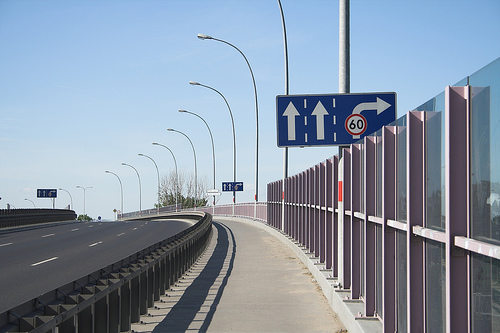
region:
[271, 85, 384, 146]
Blue arrow signs on the freeway.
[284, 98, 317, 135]
The arrows are white.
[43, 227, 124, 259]
White lines in the street.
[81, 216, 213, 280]
Railing on the freeway.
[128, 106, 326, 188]
Light poles lined up on the freeway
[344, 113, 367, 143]
Number "60" in the red circle.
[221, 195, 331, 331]
Sidewalk on the walkway of bridge.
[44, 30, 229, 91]
The sky is clear and blue.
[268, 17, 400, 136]
The sign is posted on the silver pole.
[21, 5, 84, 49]
this is the sky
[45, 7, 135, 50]
the sky is blue in color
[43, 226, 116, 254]
this is the road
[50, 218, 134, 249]
the road is clean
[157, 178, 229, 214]
this is the tree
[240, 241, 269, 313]
this is the pavement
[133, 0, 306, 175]
these are some street lights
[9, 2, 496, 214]
blue of daytime sky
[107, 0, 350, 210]
street lights on curved poles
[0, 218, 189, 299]
white lines on street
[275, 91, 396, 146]
blue sign with white arrows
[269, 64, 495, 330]
glass wall with metal beams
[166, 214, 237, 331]
shadow of guard rail on cement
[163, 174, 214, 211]
tree with no leaves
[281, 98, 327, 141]
two arrows pointing up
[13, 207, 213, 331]
guard rail on street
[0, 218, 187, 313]
street with three lanes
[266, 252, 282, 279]
part of a floor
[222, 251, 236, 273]
part of a shade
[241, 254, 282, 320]
part of a floor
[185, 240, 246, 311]
part of a shade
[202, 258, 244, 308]
part of a shade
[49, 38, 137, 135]
Sky is blue color.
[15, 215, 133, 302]
Road is grey color.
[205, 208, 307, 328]
sidewalk is grey color.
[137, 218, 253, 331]
Shadow fall on sidewalk.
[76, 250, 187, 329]
Rail is grey color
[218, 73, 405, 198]
Arrows are white color.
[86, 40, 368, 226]
Street lights are on sides of road.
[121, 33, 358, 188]
Street lights are attached to the poles.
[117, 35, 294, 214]
Poles are grey color.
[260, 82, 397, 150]
a blue and white sign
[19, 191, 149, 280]
lines on the road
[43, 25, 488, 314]
a bright and sunny day